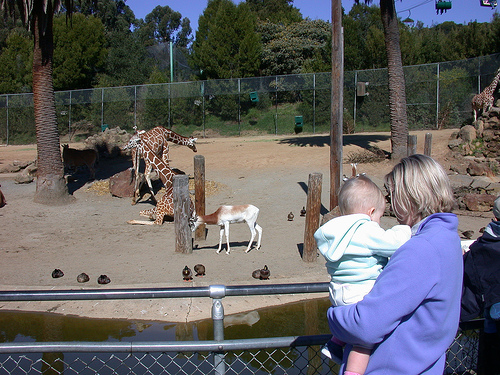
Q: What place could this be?
A: It is a zoo.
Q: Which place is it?
A: It is a zoo.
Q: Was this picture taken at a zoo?
A: Yes, it was taken in a zoo.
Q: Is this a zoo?
A: Yes, it is a zoo.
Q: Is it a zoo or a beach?
A: It is a zoo.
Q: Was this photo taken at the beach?
A: No, the picture was taken in the zoo.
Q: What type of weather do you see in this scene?
A: It is clear.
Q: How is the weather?
A: It is clear.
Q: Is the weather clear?
A: Yes, it is clear.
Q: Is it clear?
A: Yes, it is clear.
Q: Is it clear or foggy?
A: It is clear.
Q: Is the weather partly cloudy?
A: No, it is clear.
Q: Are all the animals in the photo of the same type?
A: No, they are pigeons and giraffes.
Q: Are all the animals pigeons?
A: No, there are both pigeons and giraffes.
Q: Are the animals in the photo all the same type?
A: No, they are pigeons and giraffes.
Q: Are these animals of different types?
A: Yes, they are pigeons and giraffes.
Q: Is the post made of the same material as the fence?
A: No, the post is made of wood and the fence is made of metal.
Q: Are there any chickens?
A: No, there are no chickens.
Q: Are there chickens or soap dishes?
A: No, there are no chickens or soap dishes.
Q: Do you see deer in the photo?
A: Yes, there is a deer.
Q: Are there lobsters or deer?
A: Yes, there is a deer.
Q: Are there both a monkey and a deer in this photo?
A: No, there is a deer but no monkeys.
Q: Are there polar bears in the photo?
A: No, there are no polar bears.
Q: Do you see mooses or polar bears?
A: No, there are no polar bears or mooses.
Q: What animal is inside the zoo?
A: The animal is a deer.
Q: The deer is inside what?
A: The deer is inside the zoo.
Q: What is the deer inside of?
A: The deer is inside the zoo.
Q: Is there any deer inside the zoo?
A: Yes, there is a deer inside the zoo.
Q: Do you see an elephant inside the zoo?
A: No, there is a deer inside the zoo.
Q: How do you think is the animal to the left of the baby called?
A: The animal is a deer.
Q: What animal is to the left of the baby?
A: The animal is a deer.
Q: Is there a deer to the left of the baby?
A: Yes, there is a deer to the left of the baby.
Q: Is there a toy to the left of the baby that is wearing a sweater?
A: No, there is a deer to the left of the baby.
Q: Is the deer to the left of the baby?
A: Yes, the deer is to the left of the baby.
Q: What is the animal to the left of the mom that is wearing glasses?
A: The animal is a deer.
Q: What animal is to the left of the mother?
A: The animal is a deer.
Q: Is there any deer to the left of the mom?
A: Yes, there is a deer to the left of the mom.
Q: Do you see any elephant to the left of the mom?
A: No, there is a deer to the left of the mom.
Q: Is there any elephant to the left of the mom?
A: No, there is a deer to the left of the mom.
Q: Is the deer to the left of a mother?
A: Yes, the deer is to the left of a mother.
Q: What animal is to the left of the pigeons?
A: The animal is a deer.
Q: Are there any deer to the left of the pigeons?
A: Yes, there is a deer to the left of the pigeons.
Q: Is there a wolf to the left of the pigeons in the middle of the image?
A: No, there is a deer to the left of the pigeons.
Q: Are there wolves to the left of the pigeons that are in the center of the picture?
A: No, there is a deer to the left of the pigeons.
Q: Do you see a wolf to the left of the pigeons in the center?
A: No, there is a deer to the left of the pigeons.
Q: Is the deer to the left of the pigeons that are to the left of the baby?
A: Yes, the deer is to the left of the pigeons.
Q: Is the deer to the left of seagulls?
A: No, the deer is to the left of the pigeons.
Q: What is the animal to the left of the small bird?
A: The animal is a deer.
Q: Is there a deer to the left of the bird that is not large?
A: Yes, there is a deer to the left of the bird.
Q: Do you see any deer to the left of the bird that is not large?
A: Yes, there is a deer to the left of the bird.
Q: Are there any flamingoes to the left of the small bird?
A: No, there is a deer to the left of the bird.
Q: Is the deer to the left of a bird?
A: Yes, the deer is to the left of a bird.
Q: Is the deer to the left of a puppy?
A: No, the deer is to the left of a bird.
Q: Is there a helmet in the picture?
A: No, there are no helmets.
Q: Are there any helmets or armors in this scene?
A: No, there are no helmets or armors.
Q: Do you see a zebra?
A: No, there are no zebras.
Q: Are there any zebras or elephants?
A: No, there are no zebras or elephants.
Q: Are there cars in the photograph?
A: No, there are no cars.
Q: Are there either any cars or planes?
A: No, there are no cars or planes.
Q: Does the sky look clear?
A: Yes, the sky is clear.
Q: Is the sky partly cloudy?
A: No, the sky is clear.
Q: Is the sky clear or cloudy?
A: The sky is clear.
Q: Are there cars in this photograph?
A: No, there are no cars.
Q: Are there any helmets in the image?
A: No, there are no helmets.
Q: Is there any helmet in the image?
A: No, there are no helmets.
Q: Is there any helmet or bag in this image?
A: No, there are no helmets or bags.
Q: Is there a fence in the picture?
A: Yes, there is a fence.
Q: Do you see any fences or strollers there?
A: Yes, there is a fence.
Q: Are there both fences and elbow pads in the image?
A: No, there is a fence but no elbow pads.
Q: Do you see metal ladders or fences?
A: Yes, there is a metal fence.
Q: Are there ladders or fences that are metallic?
A: Yes, the fence is metallic.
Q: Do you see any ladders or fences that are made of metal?
A: Yes, the fence is made of metal.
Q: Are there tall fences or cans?
A: Yes, there is a tall fence.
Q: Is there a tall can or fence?
A: Yes, there is a tall fence.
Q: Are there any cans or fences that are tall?
A: Yes, the fence is tall.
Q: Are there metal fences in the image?
A: Yes, there is a metal fence.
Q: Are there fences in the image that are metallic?
A: Yes, there is a fence that is metallic.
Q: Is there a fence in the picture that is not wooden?
A: Yes, there is a metallic fence.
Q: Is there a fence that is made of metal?
A: Yes, there is a fence that is made of metal.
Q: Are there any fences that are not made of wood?
A: Yes, there is a fence that is made of metal.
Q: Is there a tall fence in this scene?
A: Yes, there is a tall fence.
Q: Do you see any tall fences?
A: Yes, there is a tall fence.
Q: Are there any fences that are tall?
A: Yes, there is a fence that is tall.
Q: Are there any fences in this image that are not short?
A: Yes, there is a tall fence.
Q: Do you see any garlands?
A: No, there are no garlands.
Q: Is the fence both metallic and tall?
A: Yes, the fence is metallic and tall.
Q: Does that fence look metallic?
A: Yes, the fence is metallic.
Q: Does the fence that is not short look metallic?
A: Yes, the fence is metallic.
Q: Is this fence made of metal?
A: Yes, the fence is made of metal.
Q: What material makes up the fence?
A: The fence is made of metal.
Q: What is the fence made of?
A: The fence is made of metal.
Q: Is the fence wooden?
A: No, the fence is metallic.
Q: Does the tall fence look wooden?
A: No, the fence is metallic.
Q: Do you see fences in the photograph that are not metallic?
A: No, there is a fence but it is metallic.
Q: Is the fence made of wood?
A: No, the fence is made of metal.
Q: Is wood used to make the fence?
A: No, the fence is made of metal.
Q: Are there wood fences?
A: No, there is a fence but it is made of metal.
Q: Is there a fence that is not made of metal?
A: No, there is a fence but it is made of metal.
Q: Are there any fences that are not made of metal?
A: No, there is a fence but it is made of metal.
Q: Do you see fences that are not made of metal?
A: No, there is a fence but it is made of metal.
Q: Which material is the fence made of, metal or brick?
A: The fence is made of metal.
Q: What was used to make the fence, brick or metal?
A: The fence is made of metal.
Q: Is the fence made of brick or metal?
A: The fence is made of metal.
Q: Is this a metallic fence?
A: Yes, this is a metallic fence.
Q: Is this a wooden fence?
A: No, this is a metallic fence.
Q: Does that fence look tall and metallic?
A: Yes, the fence is tall and metallic.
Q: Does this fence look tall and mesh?
A: No, the fence is tall but metallic.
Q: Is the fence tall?
A: Yes, the fence is tall.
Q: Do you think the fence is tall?
A: Yes, the fence is tall.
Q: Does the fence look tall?
A: Yes, the fence is tall.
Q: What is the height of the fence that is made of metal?
A: The fence is tall.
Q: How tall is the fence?
A: The fence is tall.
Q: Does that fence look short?
A: No, the fence is tall.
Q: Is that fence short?
A: No, the fence is tall.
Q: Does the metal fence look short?
A: No, the fence is tall.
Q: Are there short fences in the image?
A: No, there is a fence but it is tall.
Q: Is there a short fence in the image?
A: No, there is a fence but it is tall.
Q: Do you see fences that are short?
A: No, there is a fence but it is tall.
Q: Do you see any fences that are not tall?
A: No, there is a fence but it is tall.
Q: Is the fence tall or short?
A: The fence is tall.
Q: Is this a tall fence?
A: Yes, this is a tall fence.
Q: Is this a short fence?
A: No, this is a tall fence.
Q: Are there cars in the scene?
A: No, there are no cars.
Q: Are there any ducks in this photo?
A: Yes, there is a duck.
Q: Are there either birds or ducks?
A: Yes, there is a duck.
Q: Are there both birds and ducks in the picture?
A: Yes, there are both a duck and a bird.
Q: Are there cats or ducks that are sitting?
A: Yes, the duck is sitting.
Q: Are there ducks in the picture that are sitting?
A: Yes, there is a duck that is sitting.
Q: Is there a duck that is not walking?
A: Yes, there is a duck that is sitting.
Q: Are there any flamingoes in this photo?
A: No, there are no flamingoes.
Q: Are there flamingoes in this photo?
A: No, there are no flamingoes.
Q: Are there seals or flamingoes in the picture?
A: No, there are no flamingoes or seals.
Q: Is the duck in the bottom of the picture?
A: Yes, the duck is in the bottom of the image.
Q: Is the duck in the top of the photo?
A: No, the duck is in the bottom of the image.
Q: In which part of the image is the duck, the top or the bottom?
A: The duck is in the bottom of the image.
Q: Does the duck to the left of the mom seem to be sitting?
A: Yes, the duck is sitting.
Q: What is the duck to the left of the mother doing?
A: The duck is sitting.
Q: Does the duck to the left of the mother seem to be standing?
A: No, the duck is sitting.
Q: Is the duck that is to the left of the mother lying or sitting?
A: The duck is sitting.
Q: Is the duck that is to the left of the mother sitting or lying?
A: The duck is sitting.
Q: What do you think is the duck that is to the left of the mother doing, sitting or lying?
A: The duck is sitting.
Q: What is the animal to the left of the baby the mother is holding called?
A: The animal is a duck.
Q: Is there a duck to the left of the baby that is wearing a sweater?
A: Yes, there is a duck to the left of the baby.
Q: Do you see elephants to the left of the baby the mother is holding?
A: No, there is a duck to the left of the baby.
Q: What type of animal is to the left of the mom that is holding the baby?
A: The animal is a duck.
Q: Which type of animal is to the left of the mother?
A: The animal is a duck.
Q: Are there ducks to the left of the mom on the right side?
A: Yes, there is a duck to the left of the mother.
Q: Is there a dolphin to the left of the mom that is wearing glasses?
A: No, there is a duck to the left of the mom.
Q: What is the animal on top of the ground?
A: The animal is a duck.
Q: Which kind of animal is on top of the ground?
A: The animal is a duck.